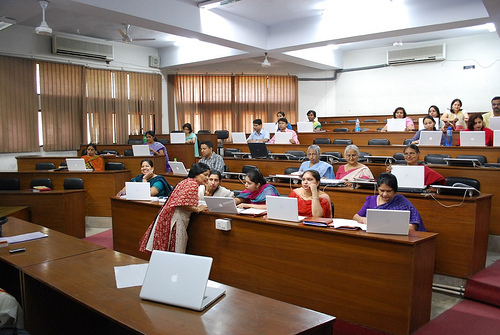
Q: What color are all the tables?
A: Brown.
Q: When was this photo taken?
A: Daytime.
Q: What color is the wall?
A: White.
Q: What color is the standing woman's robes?
A: Red.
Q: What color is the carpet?
A: Red.